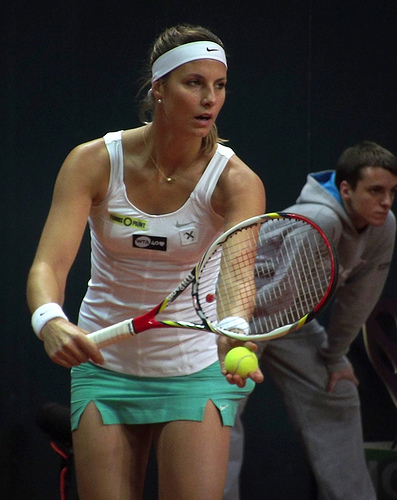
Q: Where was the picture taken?
A: Tennis court.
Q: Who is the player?
A: A woman.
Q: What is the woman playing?
A: Tennis.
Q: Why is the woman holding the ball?
A: To serve.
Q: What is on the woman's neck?
A: A necklace.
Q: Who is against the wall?
A: A boy.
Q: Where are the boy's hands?
A: On knees.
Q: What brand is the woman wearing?
A: Nike.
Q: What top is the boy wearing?
A: A hoodie sweatshirt.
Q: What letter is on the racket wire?
A: W.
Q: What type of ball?
A: Tennis.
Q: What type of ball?
A: Tennis.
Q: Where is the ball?
A: In hand.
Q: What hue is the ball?
A: Yellow.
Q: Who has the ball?
A: Tennis player.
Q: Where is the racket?
A: Behind ball.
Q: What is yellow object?
A: Ball.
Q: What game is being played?
A: Tennis.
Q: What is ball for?
A: Tennis.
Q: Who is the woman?
A: Tennis player.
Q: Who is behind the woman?
A: A man in a workout suit.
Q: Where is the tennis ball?
A: In the woman's left hand.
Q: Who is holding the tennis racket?
A: The woman in front.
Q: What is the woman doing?
A: Getting ready to serve the ball.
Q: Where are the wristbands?
A: On the woman's wrists.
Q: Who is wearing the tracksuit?
A: The man.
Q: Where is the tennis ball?
A: In the woman's hand.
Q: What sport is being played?
A: Tennis.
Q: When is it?
A: Day time.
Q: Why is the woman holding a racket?
A: She is playing tennis.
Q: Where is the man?
A: Behind the woman.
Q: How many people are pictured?
A: Two.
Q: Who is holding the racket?
A: The woman.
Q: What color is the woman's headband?
A: White.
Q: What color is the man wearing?
A: Gray.